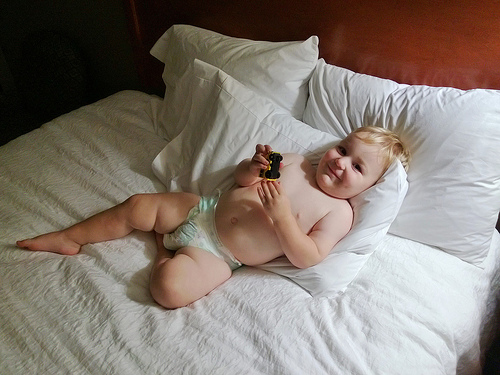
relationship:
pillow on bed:
[160, 28, 498, 254] [2, 88, 500, 374]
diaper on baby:
[162, 197, 232, 258] [63, 127, 414, 290]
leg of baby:
[34, 194, 210, 249] [63, 127, 414, 290]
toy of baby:
[266, 152, 281, 178] [63, 127, 414, 290]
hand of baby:
[251, 177, 293, 223] [63, 127, 414, 290]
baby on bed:
[63, 127, 414, 290] [2, 88, 500, 374]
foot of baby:
[19, 235, 94, 252] [63, 127, 414, 290]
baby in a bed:
[63, 127, 414, 290] [2, 88, 500, 374]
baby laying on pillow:
[63, 127, 414, 290] [160, 28, 498, 254]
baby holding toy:
[63, 127, 414, 290] [266, 152, 281, 178]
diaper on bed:
[162, 197, 232, 258] [2, 88, 500, 374]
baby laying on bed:
[63, 127, 414, 290] [2, 88, 500, 374]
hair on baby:
[355, 126, 412, 161] [63, 127, 414, 290]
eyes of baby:
[339, 147, 365, 173] [63, 127, 414, 290]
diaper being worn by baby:
[162, 197, 232, 258] [63, 127, 414, 290]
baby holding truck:
[63, 127, 414, 290] [257, 152, 284, 180]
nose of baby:
[336, 158, 348, 168] [63, 127, 414, 290]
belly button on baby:
[230, 214, 243, 229] [63, 127, 414, 290]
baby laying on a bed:
[63, 127, 414, 290] [2, 88, 500, 374]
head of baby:
[321, 128, 392, 198] [63, 127, 414, 290]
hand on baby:
[251, 177, 293, 223] [63, 127, 414, 290]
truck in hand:
[257, 152, 284, 180] [251, 177, 293, 223]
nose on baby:
[336, 158, 348, 168] [63, 127, 414, 290]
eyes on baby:
[339, 147, 365, 173] [63, 127, 414, 290]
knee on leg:
[126, 195, 146, 206] [34, 194, 210, 249]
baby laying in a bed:
[63, 127, 414, 290] [2, 88, 500, 374]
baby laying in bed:
[63, 127, 414, 290] [2, 88, 500, 374]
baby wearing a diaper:
[63, 127, 414, 290] [162, 197, 232, 258]